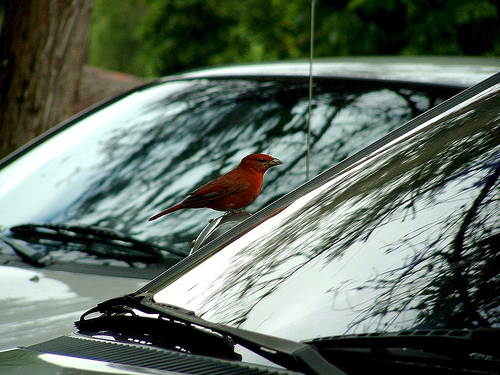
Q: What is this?
A: A bird.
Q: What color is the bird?
A: Red.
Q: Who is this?
A: No one.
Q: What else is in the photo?
A: Cars.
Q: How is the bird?
A: Motionless.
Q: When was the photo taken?
A: Daytime.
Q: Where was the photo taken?
A: In a parking lot.